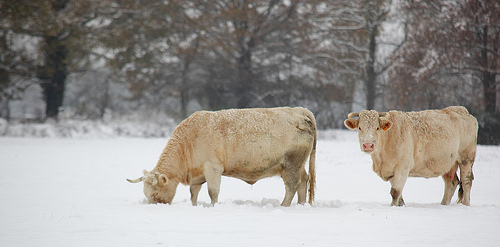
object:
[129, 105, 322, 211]
cow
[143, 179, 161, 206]
face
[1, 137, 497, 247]
snow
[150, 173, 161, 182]
horns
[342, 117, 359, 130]
ears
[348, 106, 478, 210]
cow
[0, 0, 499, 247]
camera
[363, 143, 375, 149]
nose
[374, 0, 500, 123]
trees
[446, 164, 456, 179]
udder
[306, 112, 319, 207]
tail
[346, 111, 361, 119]
horns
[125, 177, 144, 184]
horns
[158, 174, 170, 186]
ear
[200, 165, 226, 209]
left front leg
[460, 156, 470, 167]
patches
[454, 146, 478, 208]
left hind leg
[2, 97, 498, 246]
field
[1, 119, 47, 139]
bushes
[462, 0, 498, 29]
leaves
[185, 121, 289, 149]
hair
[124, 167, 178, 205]
cow's head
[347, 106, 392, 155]
head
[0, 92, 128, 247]
left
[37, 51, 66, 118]
trunks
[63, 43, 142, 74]
branches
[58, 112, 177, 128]
foilage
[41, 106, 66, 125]
tree base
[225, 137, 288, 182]
belly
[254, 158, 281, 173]
marks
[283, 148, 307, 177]
thighs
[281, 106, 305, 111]
bump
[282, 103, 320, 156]
rump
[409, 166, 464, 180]
belly bottom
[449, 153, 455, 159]
point